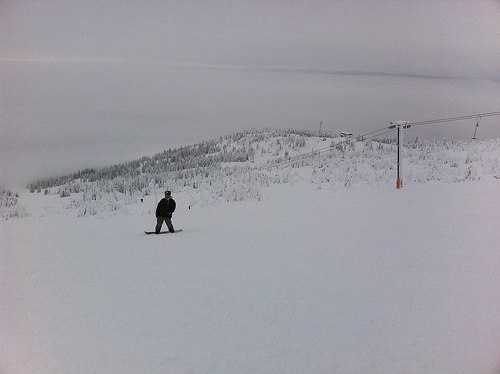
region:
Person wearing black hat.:
[159, 189, 174, 191]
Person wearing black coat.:
[156, 199, 176, 213]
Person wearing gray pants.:
[150, 215, 181, 226]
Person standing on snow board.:
[138, 218, 210, 250]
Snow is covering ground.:
[276, 230, 393, 322]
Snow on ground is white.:
[61, 278, 139, 343]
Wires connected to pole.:
[404, 105, 474, 130]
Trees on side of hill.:
[248, 130, 288, 197]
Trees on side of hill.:
[74, 156, 145, 202]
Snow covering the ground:
[14, 308, 61, 354]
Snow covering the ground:
[94, 271, 136, 315]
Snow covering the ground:
[158, 332, 175, 358]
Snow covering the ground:
[167, 266, 207, 315]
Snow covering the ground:
[258, 257, 297, 299]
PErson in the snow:
[113, 184, 204, 280]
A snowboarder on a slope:
[137, 183, 197, 243]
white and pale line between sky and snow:
[1, 48, 487, 78]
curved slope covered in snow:
[7, 120, 492, 210]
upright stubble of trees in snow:
[30, 125, 380, 206]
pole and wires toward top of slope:
[260, 100, 492, 191]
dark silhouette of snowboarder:
[145, 185, 185, 237]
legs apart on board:
[140, 186, 180, 232]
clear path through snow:
[0, 175, 75, 220]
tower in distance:
[467, 117, 479, 142]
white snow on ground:
[439, 223, 466, 263]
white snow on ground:
[355, 251, 396, 293]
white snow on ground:
[346, 250, 371, 285]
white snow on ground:
[309, 295, 355, 359]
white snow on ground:
[264, 274, 288, 323]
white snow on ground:
[256, 213, 303, 263]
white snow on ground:
[194, 241, 234, 279]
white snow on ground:
[156, 266, 186, 301]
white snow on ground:
[106, 266, 140, 316]